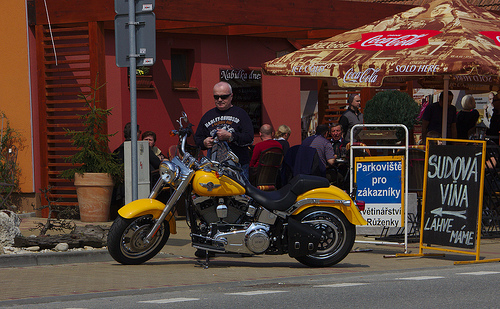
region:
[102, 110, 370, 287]
The motorcycle is black and yellow.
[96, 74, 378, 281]
A man is standing on the other side of the motorcycle.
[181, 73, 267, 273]
The man is wearing sunglasses.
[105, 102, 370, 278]
The motorcycle has two tires.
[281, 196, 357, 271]
The tire is round.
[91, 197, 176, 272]
The tire is round.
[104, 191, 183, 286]
The tire is black.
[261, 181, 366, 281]
The tire is black.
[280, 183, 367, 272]
The tire is inflated.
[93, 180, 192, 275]
The tire is inflated.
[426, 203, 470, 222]
White chalk arrow with a split end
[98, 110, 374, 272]
Yellow Harley Davidson Motorcycle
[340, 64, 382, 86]
Coca Cola logo on the umbrella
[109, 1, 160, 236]
Back of two street signs on a pole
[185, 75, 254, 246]
Man wearing a Harley Davidson shirt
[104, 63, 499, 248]
Group of people eating outside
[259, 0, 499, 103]
Sepia color photo umbrella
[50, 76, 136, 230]
Plant in a large orange pot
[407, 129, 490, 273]
Chalkboard sign with Sudova vina written on it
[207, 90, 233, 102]
Pair of black sunglasses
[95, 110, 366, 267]
Motorcycle is parked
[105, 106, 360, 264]
Yellow motorcycle is parked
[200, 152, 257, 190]
Man is wearing pants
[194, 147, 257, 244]
Man is wearing blue pants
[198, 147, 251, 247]
Man is wearing jeans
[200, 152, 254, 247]
Man is wearing blue jeans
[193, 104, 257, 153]
Man is wearing a shirt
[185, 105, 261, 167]
Man is wearing a black shirt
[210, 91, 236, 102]
Man is wearing sunglasses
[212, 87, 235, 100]
Man is wearing black sunglasses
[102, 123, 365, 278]
a black yellow and silver bike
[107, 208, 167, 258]
the rubber wheel of a bike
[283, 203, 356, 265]
the rubber wheel of a bike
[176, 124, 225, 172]
the silver handlebars of a bike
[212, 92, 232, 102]
the black sunglasses of the man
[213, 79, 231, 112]
the bald head of the man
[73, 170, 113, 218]
the large brown plant pot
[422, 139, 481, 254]
the large chalkboard sign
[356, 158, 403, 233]
the blue and white sign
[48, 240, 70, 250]
a white small stone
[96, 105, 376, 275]
motorcycle parked on a street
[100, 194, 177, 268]
front wheel on a motorcycle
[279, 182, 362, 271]
rear wheel on a motorcycle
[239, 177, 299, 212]
black seat on a motorcycle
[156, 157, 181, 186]
front headlight on a motorcycle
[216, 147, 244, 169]
rear view mirror on a motorcycle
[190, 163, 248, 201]
yellow gas tank on a motorcycle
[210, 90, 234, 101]
glasses on a persons face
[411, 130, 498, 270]
advertising sign on the ground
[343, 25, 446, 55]
red and white logo on a tent